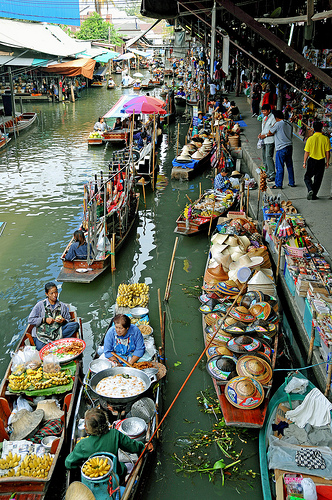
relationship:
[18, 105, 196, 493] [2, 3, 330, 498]
water in canal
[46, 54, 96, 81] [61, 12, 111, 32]
covering by building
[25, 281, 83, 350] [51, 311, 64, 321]
woman holding food.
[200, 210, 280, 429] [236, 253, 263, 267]
boat full of hat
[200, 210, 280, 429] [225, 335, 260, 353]
boat full of hat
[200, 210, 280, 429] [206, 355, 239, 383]
boat full of hat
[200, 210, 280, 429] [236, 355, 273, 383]
boat full of hat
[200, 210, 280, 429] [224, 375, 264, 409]
boat full of hat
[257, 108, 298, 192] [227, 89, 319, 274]
man standing on pier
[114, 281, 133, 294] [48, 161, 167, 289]
bananas in bunches on a boat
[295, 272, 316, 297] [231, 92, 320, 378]
books stacked on pier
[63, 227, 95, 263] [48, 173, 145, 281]
woman relaxing in boat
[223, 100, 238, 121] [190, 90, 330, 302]
people sitting by pier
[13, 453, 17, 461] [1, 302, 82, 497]
banana on boat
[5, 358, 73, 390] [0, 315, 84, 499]
bananas on boat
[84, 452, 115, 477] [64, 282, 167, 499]
bananas on boat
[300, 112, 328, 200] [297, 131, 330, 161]
man in yellow shirt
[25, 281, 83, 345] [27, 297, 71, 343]
woman wearing shirt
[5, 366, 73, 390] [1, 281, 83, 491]
bananas on boat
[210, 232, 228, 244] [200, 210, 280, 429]
hat on boat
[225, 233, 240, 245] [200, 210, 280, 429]
hat on boat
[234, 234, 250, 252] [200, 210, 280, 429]
hat on boat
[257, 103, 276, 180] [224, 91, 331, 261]
man standing on platform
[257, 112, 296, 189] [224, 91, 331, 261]
man standing on platform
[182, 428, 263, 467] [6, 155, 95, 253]
leaves in water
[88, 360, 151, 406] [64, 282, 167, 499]
bowl on boat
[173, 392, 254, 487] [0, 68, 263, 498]
vegetation in water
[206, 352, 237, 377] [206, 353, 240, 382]
blue decal on black hat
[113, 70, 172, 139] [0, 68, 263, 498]
umbrellas near water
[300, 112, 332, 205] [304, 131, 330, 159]
man wearing shirt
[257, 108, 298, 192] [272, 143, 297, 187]
man wearing blue jeans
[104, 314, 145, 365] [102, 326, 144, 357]
woman wearing shirt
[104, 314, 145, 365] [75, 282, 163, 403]
woman in boat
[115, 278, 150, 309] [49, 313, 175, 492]
bananas on boat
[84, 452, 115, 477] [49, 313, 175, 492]
bananas on boat